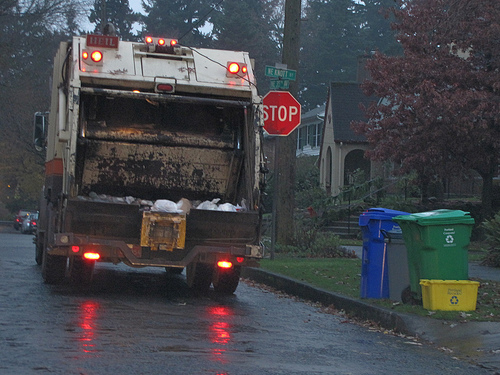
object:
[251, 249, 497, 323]
grass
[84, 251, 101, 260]
light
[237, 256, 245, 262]
light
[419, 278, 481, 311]
bin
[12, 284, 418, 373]
ground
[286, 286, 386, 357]
gutter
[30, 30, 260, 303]
tryck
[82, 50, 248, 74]
lights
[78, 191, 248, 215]
garbage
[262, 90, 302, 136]
sign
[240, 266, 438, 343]
grey curb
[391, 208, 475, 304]
bin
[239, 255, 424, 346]
leaves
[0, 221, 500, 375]
road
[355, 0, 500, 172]
leaves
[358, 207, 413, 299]
bin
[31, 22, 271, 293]
garbage truck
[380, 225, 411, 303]
trash can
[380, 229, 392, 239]
handle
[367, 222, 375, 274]
blue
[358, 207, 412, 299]
trash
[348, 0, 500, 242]
tree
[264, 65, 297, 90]
sign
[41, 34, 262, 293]
back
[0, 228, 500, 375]
street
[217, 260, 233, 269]
light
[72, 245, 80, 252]
light